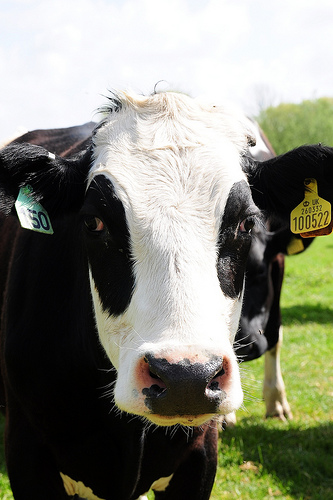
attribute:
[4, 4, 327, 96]
sky — blue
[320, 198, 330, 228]
number — black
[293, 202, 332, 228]
number — Black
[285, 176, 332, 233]
tag — yellow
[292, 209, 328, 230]
number — black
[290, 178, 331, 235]
tag — yellow, black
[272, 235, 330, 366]
grass — green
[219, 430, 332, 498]
grass — green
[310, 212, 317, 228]
number — black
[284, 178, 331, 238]
tag — yellow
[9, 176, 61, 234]
tag — blue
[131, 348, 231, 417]
nose — pink, Black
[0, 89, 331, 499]
dairy cow — Black, white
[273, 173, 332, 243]
tag — yellow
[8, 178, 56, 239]
tag — blue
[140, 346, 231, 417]
nose — black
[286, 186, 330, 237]
tag — yellow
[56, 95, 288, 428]
face — white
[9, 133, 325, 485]
cow — black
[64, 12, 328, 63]
sky — clear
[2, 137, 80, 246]
ear — black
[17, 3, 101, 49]
cloud — white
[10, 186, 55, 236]
tag — teal, dark blue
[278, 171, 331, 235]
tag — yellow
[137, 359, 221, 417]
nose — black